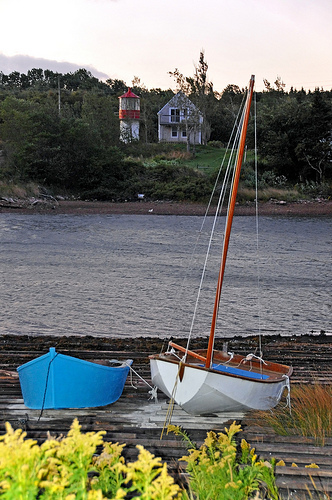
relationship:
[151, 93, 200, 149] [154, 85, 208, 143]
gray story building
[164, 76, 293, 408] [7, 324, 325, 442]
boat on dock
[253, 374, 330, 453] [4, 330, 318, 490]
weeds on boards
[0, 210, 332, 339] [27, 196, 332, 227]
lake and shoreline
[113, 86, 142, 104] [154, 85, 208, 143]
red light building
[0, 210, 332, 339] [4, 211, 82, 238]
lake with ripples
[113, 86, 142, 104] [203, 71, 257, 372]
red boat pole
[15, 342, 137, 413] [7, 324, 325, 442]
rafts on dock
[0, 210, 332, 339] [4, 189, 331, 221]
lake and shore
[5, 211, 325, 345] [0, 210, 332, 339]
blue smooth lake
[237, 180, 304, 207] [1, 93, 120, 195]
grass and shrubbery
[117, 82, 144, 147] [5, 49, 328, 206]
house near forest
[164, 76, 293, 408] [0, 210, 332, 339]
boat near lake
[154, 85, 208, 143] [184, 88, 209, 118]
building with roof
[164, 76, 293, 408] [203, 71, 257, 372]
boat with pole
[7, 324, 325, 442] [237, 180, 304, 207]
dock with grass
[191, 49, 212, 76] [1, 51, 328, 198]
green thick trees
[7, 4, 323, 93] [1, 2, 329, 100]
white pale sky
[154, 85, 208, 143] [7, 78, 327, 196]
building on hill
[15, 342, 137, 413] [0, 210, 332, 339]
rafts on lake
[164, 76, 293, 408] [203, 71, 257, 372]
boat has pole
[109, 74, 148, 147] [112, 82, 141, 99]
house has top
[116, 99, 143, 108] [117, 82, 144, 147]
windows surround house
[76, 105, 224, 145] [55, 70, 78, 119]
fence surrounds light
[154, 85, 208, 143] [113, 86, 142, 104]
building white red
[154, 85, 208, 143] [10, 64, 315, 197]
building in back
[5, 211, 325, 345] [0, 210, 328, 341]
blue calm lake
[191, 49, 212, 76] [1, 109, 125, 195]
green light shrubbery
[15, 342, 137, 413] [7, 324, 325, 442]
rafts in dock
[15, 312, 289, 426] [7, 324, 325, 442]
rafts in dock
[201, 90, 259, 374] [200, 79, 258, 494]
large orange pole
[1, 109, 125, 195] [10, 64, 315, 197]
shrubbery in back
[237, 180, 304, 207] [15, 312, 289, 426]
grass at rafts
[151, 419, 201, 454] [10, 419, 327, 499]
tip of plant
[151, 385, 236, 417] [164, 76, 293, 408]
bottom of boat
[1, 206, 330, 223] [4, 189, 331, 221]
edge of shore